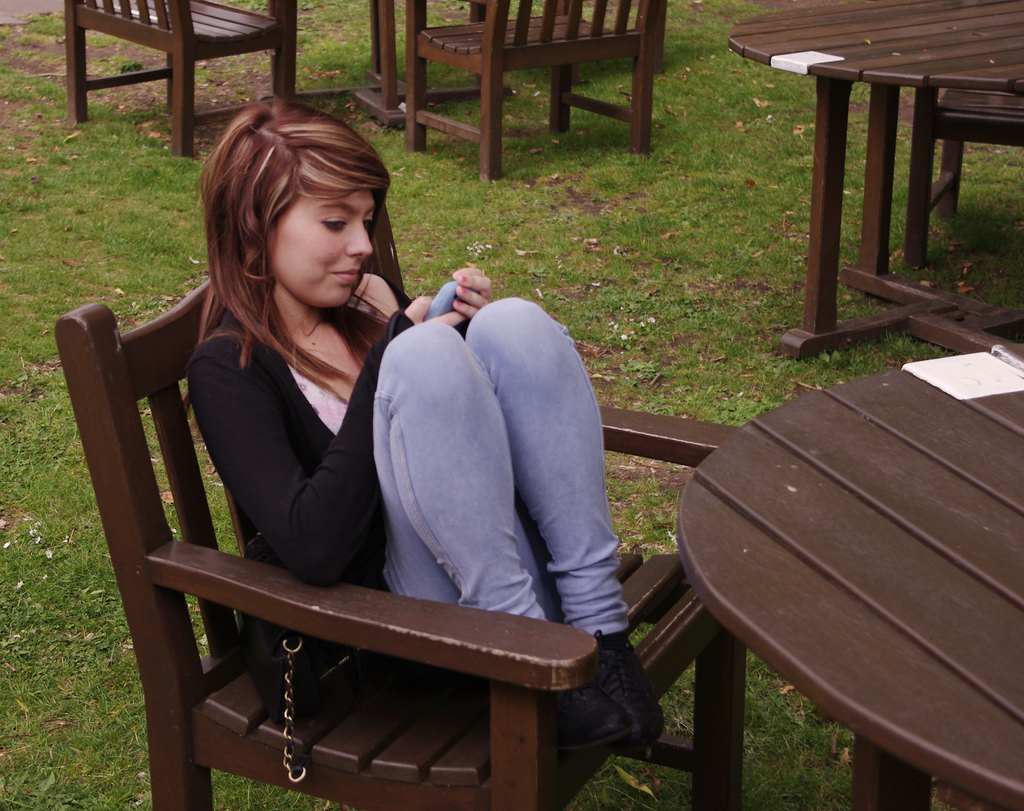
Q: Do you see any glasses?
A: No, there are no glasses.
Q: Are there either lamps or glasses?
A: No, there are no glasses or lamps.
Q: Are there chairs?
A: Yes, there is a chair.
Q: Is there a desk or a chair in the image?
A: Yes, there is a chair.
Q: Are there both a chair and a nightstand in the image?
A: No, there is a chair but no nightstands.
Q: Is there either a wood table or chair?
A: Yes, there is a wood chair.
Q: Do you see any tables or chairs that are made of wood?
A: Yes, the chair is made of wood.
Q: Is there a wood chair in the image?
A: Yes, there is a chair that is made of wood.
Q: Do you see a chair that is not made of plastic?
A: Yes, there is a chair that is made of wood.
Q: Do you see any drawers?
A: No, there are no drawers.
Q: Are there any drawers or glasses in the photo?
A: No, there are no drawers or glasses.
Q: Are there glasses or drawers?
A: No, there are no drawers or glasses.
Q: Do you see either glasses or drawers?
A: No, there are no drawers or glasses.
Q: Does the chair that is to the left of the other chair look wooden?
A: Yes, the chair is wooden.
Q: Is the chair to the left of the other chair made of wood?
A: Yes, the chair is made of wood.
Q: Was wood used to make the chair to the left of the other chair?
A: Yes, the chair is made of wood.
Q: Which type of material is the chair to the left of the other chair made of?
A: The chair is made of wood.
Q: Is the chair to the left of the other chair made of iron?
A: No, the chair is made of wood.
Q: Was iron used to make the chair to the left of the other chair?
A: No, the chair is made of wood.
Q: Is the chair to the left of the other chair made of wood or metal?
A: The chair is made of wood.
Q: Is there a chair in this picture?
A: Yes, there is a chair.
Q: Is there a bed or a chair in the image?
A: Yes, there is a chair.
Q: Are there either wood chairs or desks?
A: Yes, there is a wood chair.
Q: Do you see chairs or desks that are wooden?
A: Yes, the chair is wooden.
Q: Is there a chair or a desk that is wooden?
A: Yes, the chair is wooden.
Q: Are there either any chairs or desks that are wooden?
A: Yes, the chair is wooden.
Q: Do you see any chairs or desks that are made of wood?
A: Yes, the chair is made of wood.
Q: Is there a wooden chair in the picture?
A: Yes, there is a wood chair.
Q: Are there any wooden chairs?
A: Yes, there is a wood chair.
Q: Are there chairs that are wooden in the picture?
A: Yes, there is a wood chair.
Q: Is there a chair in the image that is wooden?
A: Yes, there is a chair that is wooden.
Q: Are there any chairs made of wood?
A: Yes, there is a chair that is made of wood.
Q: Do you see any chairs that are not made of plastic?
A: Yes, there is a chair that is made of wood.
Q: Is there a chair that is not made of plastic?
A: Yes, there is a chair that is made of wood.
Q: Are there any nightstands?
A: No, there are no nightstands.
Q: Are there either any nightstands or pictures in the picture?
A: No, there are no nightstands or pictures.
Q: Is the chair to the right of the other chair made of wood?
A: Yes, the chair is made of wood.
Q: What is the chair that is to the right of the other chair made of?
A: The chair is made of wood.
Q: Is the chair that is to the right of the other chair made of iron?
A: No, the chair is made of wood.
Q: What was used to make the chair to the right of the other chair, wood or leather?
A: The chair is made of wood.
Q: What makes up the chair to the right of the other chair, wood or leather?
A: The chair is made of wood.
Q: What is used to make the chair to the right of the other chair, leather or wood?
A: The chair is made of wood.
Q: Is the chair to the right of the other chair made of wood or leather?
A: The chair is made of wood.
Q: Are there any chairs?
A: Yes, there is a chair.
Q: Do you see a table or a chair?
A: Yes, there is a chair.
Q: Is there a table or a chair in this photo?
A: Yes, there is a chair.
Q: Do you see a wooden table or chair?
A: Yes, there is a wood chair.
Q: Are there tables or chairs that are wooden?
A: Yes, the chair is wooden.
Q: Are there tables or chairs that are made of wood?
A: Yes, the chair is made of wood.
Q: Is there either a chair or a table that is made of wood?
A: Yes, the chair is made of wood.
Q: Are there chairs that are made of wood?
A: Yes, there is a chair that is made of wood.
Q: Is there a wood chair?
A: Yes, there is a chair that is made of wood.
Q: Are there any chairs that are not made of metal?
A: Yes, there is a chair that is made of wood.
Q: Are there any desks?
A: No, there are no desks.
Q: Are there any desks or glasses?
A: No, there are no desks or glasses.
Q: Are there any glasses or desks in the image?
A: No, there are no desks or glasses.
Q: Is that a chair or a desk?
A: That is a chair.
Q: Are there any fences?
A: No, there are no fences.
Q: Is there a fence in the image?
A: No, there are no fences.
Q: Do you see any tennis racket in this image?
A: No, there are no rackets.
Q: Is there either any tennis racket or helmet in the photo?
A: No, there are no rackets or helmets.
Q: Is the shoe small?
A: Yes, the shoe is small.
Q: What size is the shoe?
A: The shoe is small.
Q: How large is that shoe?
A: The shoe is small.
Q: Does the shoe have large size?
A: No, the shoe is small.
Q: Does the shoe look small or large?
A: The shoe is small.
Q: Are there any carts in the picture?
A: No, there are no carts.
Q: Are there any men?
A: No, there are no men.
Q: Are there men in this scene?
A: No, there are no men.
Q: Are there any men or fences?
A: No, there are no men or fences.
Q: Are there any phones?
A: Yes, there is a phone.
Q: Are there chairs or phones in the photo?
A: Yes, there is a phone.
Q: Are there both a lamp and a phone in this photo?
A: No, there is a phone but no lamps.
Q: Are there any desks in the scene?
A: No, there are no desks.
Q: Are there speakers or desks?
A: No, there are no desks or speakers.